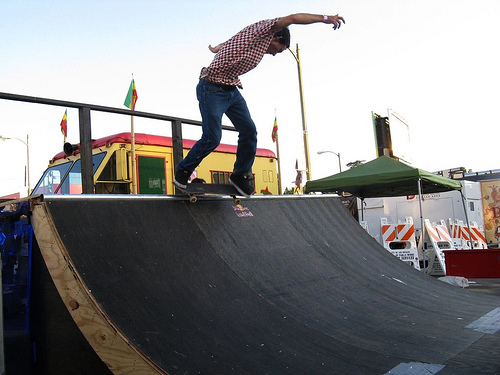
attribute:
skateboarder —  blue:
[170, 7, 342, 208]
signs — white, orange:
[373, 205, 499, 267]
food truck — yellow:
[26, 71, 283, 196]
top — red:
[51, 131, 278, 160]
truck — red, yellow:
[22, 126, 282, 206]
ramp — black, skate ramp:
[0, 92, 497, 373]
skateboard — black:
[171, 175, 244, 204]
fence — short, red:
[445, 249, 498, 278]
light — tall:
[281, 42, 316, 192]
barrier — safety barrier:
[377, 216, 422, 277]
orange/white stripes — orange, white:
[382, 222, 417, 239]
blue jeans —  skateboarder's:
[180, 78, 258, 166]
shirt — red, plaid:
[200, 18, 272, 85]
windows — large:
[33, 160, 99, 192]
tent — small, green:
[323, 151, 479, 271]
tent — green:
[301, 149, 462, 197]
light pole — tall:
[270, 40, 332, 194]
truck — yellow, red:
[14, 132, 306, 217]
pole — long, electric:
[286, 35, 322, 193]